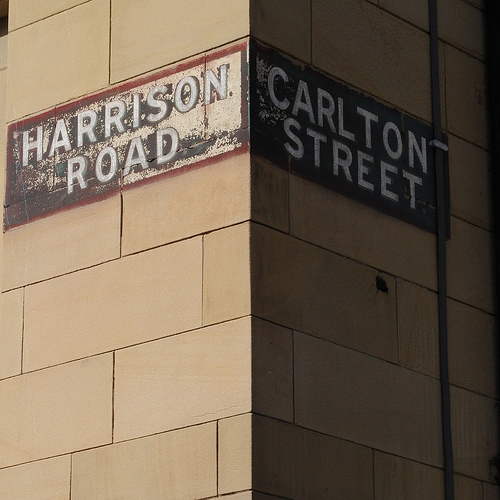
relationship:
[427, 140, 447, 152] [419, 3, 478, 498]
bracket on pole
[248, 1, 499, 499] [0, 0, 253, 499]
shade on wall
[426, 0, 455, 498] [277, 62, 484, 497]
long pole on wall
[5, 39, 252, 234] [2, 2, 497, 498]
sign on building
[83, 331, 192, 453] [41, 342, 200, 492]
sun reflected on building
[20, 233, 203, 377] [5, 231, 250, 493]
beige brick on wall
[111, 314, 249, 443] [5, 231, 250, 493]
brick on wall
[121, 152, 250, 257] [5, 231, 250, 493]
brick on wall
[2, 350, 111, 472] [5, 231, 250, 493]
brick on wall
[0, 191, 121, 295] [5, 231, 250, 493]
beige brick on wall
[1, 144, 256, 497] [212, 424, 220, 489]
wall has crack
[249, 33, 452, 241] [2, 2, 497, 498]
sign on building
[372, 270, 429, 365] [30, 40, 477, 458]
stain on building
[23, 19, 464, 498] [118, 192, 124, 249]
building has gap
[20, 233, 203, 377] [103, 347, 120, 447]
beige brick has gaps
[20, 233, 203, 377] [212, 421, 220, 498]
beige brick has crack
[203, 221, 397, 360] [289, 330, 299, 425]
brick has gap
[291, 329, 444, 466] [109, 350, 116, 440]
brick has gap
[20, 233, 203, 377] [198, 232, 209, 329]
beige brick has gap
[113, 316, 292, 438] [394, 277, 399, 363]
brick has gap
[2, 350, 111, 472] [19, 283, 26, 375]
brick has gap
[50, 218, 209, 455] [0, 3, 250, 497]
light on building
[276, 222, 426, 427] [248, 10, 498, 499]
shade on building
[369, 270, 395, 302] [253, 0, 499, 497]
hole in wall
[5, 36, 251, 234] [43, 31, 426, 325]
sign on building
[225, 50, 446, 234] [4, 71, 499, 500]
sign on building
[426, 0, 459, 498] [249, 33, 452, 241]
long pole along sign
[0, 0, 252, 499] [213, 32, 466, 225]
wall below sign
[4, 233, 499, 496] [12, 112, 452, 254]
wall below sign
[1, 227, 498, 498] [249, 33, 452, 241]
beige brick below sign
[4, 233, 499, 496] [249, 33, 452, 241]
wall below sign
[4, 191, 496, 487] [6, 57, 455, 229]
beige brick below street sign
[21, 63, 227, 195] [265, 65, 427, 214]
harrison road on carlton street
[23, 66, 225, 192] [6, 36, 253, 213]
harrison road on sign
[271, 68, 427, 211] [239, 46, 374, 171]
carlton street on sign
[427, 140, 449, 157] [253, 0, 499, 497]
bracket on wall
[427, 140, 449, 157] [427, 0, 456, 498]
bracket on cord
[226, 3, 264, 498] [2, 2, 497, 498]
corner on building